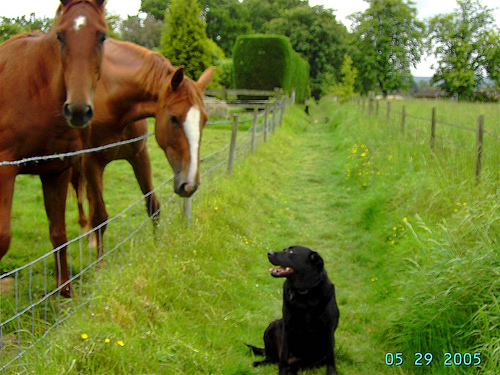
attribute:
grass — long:
[0, 92, 499, 372]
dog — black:
[241, 233, 353, 374]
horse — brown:
[4, 2, 113, 312]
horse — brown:
[57, 34, 211, 270]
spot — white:
[177, 98, 207, 192]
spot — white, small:
[72, 13, 88, 27]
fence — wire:
[1, 94, 304, 352]